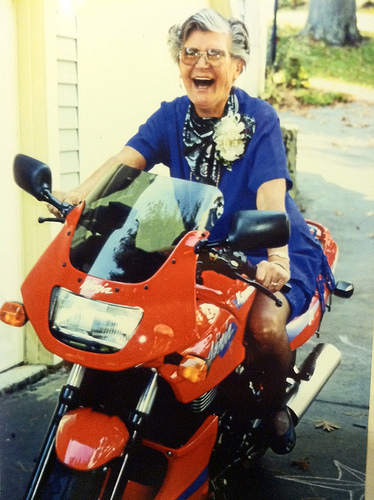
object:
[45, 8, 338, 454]
woman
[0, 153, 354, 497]
motorcycle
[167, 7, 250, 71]
hair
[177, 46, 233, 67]
glasses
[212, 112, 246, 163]
corsage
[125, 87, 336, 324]
dress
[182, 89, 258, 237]
scarf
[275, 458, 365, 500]
chalk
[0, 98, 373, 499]
concrete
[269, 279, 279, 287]
ring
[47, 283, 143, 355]
light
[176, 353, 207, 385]
signal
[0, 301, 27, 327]
signal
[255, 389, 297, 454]
shoe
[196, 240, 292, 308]
handlebars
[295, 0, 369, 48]
trunk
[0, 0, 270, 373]
house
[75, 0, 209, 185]
door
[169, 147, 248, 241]
chest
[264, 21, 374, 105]
grass